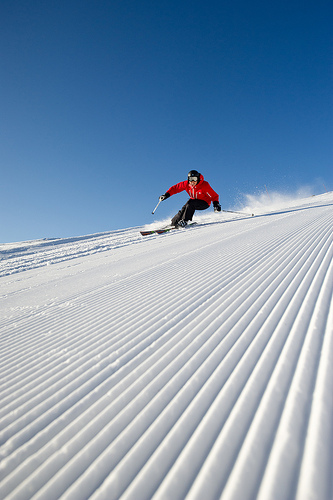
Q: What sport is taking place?
A: Skiing.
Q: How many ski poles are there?
A: Two.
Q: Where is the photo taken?
A: Mountains.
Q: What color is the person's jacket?
A: Red.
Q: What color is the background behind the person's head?
A: Blue.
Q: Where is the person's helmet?
A: Head.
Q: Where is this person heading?
A: Downhill.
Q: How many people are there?
A: One.